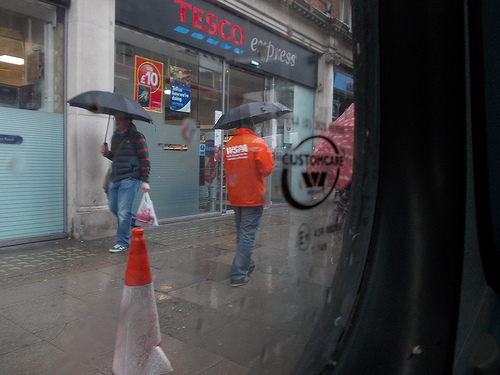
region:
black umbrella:
[74, 81, 151, 141]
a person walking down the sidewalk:
[100, 113, 143, 257]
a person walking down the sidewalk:
[224, 122, 275, 284]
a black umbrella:
[70, 93, 157, 122]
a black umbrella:
[215, 96, 290, 119]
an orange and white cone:
[115, 224, 170, 373]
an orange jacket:
[222, 131, 272, 202]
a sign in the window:
[133, 53, 163, 111]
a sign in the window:
[170, 63, 193, 114]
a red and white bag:
[139, 189, 159, 226]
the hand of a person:
[141, 183, 153, 193]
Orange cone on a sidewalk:
[93, 203, 210, 373]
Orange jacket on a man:
[207, 122, 302, 252]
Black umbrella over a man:
[198, 79, 282, 149]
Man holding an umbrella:
[76, 76, 155, 168]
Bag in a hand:
[126, 184, 183, 236]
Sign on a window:
[269, 100, 366, 293]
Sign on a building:
[178, 0, 328, 85]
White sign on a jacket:
[223, 145, 260, 170]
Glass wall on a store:
[127, 37, 300, 202]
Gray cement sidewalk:
[136, 235, 286, 347]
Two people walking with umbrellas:
[62, 71, 292, 317]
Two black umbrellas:
[64, 81, 294, 196]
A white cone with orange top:
[100, 221, 193, 373]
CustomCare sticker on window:
[266, 118, 363, 268]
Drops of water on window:
[212, 233, 382, 351]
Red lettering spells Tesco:
[166, 1, 265, 69]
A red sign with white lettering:
[123, 48, 175, 118]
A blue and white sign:
[166, 81, 210, 133]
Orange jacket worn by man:
[214, 128, 285, 221]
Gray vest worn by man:
[98, 131, 146, 191]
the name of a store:
[175, 0, 309, 72]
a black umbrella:
[67, 86, 153, 156]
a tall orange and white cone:
[110, 221, 188, 373]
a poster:
[132, 52, 167, 114]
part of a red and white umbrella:
[310, 103, 360, 193]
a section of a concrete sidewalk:
[7, 289, 92, 332]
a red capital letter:
[175, 2, 197, 29]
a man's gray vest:
[110, 129, 142, 179]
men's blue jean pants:
[230, 202, 260, 284]